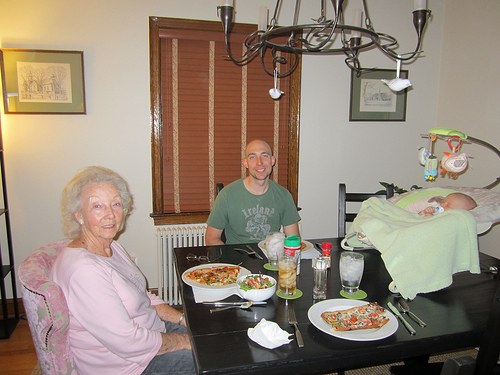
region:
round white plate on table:
[176, 260, 252, 286]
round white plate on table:
[307, 297, 397, 342]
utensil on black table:
[287, 308, 306, 348]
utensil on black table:
[386, 299, 416, 336]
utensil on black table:
[396, 295, 426, 327]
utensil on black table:
[207, 303, 251, 313]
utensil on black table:
[234, 244, 256, 255]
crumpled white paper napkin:
[245, 317, 293, 348]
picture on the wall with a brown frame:
[1, 45, 85, 113]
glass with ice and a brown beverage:
[276, 253, 298, 293]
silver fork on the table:
[286, 305, 304, 347]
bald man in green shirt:
[206, 138, 301, 243]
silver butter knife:
[386, 298, 416, 336]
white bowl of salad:
[236, 270, 276, 302]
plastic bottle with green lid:
[284, 235, 300, 270]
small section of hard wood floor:
[1, 296, 35, 373]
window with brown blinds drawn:
[146, 15, 300, 220]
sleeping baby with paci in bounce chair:
[359, 190, 476, 240]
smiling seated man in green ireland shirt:
[209, 138, 302, 245]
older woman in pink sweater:
[51, 165, 185, 373]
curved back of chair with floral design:
[21, 235, 76, 373]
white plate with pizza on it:
[310, 302, 400, 342]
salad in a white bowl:
[237, 273, 274, 299]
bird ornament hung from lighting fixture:
[382, 60, 412, 91]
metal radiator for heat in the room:
[158, 227, 209, 300]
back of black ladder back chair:
[339, 186, 379, 237]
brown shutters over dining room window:
[162, 31, 291, 215]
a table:
[196, 334, 233, 364]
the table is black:
[196, 329, 239, 366]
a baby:
[425, 190, 475, 214]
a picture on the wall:
[3, 48, 84, 111]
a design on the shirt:
[236, 200, 278, 237]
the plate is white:
[356, 328, 377, 341]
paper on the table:
[247, 315, 287, 351]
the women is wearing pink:
[67, 268, 142, 339]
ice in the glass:
[341, 253, 363, 284]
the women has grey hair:
[63, 188, 80, 210]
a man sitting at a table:
[204, 137, 300, 245]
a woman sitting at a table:
[50, 165, 194, 374]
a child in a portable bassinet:
[340, 183, 498, 295]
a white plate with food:
[308, 297, 400, 342]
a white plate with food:
[178, 262, 252, 290]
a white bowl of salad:
[232, 272, 276, 302]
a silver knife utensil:
[384, 300, 416, 335]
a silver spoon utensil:
[393, 296, 423, 328]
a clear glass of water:
[337, 248, 364, 290]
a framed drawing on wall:
[0, 46, 87, 117]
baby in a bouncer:
[418, 189, 478, 219]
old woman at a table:
[56, 160, 196, 373]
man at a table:
[201, 130, 307, 253]